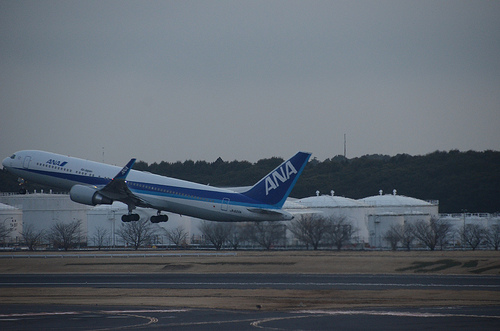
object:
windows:
[10, 154, 16, 160]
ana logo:
[263, 159, 297, 194]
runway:
[0, 271, 498, 290]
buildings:
[355, 188, 440, 246]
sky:
[1, 1, 499, 166]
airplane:
[0, 149, 311, 224]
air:
[1, 2, 171, 101]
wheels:
[148, 213, 158, 224]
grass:
[0, 252, 499, 275]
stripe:
[2, 166, 267, 205]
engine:
[66, 183, 113, 208]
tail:
[241, 149, 314, 209]